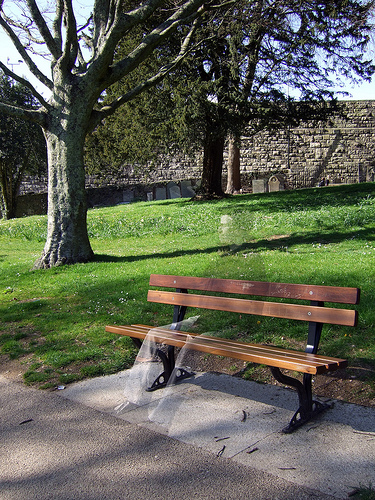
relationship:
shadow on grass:
[91, 221, 373, 272] [144, 195, 329, 264]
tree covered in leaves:
[92, 0, 374, 200] [106, 6, 369, 151]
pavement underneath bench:
[61, 354, 364, 498] [98, 265, 364, 424]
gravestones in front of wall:
[101, 145, 362, 208] [0, 99, 372, 216]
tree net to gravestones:
[84, 0, 352, 202] [96, 152, 299, 209]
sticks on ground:
[199, 396, 291, 475] [2, 387, 374, 498]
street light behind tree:
[1, 48, 22, 73] [0, 2, 220, 273]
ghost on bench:
[158, 197, 280, 302] [83, 249, 368, 432]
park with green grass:
[0, 1, 371, 498] [37, 379, 54, 390]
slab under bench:
[52, 358, 374, 495] [101, 271, 359, 434]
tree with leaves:
[92, 0, 374, 200] [179, 75, 226, 95]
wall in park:
[3, 90, 373, 221] [0, 179, 372, 499]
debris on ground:
[214, 441, 231, 464] [1, 192, 373, 498]